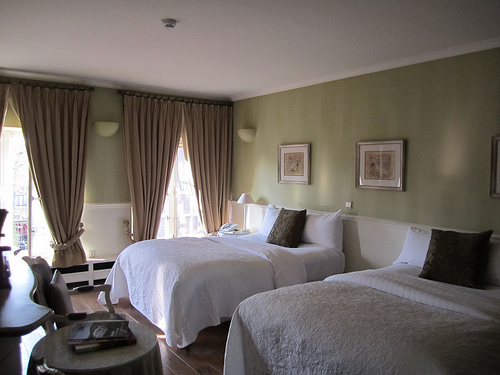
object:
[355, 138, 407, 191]
artwork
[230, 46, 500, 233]
wall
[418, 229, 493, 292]
pillow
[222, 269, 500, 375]
bedspread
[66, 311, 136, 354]
books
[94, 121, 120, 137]
light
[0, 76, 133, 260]
wall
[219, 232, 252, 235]
table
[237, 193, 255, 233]
lamp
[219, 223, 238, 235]
phone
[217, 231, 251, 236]
nightstand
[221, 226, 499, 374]
bed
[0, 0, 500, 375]
bedroom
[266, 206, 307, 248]
pillow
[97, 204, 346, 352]
bed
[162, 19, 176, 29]
sprinkler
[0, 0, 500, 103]
ceiling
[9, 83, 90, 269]
curtain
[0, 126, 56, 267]
window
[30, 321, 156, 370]
table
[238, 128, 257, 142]
light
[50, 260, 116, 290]
radiator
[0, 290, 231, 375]
floor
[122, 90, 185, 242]
curtains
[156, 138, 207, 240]
window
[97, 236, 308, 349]
bedspread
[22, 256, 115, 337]
chair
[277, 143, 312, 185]
picture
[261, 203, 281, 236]
pillows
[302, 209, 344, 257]
pillow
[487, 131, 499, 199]
picture